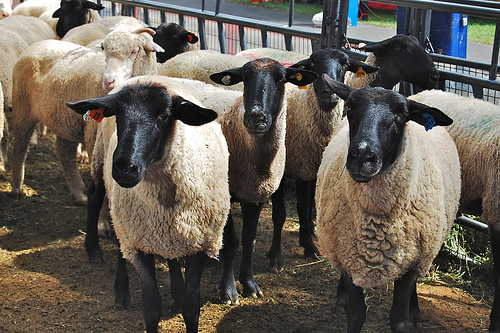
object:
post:
[404, 7, 433, 54]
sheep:
[0, 0, 500, 333]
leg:
[346, 276, 370, 333]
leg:
[390, 270, 418, 318]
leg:
[295, 181, 312, 247]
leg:
[269, 193, 286, 252]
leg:
[487, 233, 500, 319]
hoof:
[83, 238, 105, 264]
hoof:
[10, 181, 24, 198]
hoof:
[68, 182, 88, 206]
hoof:
[236, 275, 264, 299]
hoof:
[220, 275, 240, 307]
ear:
[208, 66, 243, 86]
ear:
[65, 94, 114, 118]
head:
[321, 73, 454, 183]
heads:
[95, 28, 156, 92]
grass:
[223, 0, 499, 45]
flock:
[0, 0, 499, 333]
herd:
[357, 33, 441, 89]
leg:
[126, 252, 164, 333]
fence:
[95, 0, 499, 107]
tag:
[83, 108, 105, 124]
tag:
[221, 75, 231, 86]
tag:
[295, 73, 307, 90]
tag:
[421, 112, 436, 131]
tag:
[356, 60, 366, 78]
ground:
[0, 246, 500, 333]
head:
[65, 81, 218, 188]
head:
[209, 57, 319, 132]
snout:
[103, 75, 117, 91]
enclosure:
[0, 0, 500, 333]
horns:
[132, 27, 156, 36]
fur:
[0, 0, 500, 295]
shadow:
[10, 234, 214, 324]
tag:
[188, 33, 195, 42]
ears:
[209, 67, 243, 85]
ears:
[287, 68, 319, 86]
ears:
[347, 59, 379, 74]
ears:
[186, 32, 199, 43]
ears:
[173, 95, 219, 125]